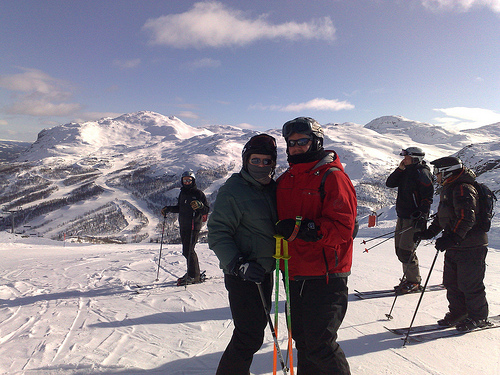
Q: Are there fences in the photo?
A: No, there are no fences.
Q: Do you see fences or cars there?
A: No, there are no fences or cars.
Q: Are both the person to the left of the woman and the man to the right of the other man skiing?
A: Yes, both the person and the man are skiing.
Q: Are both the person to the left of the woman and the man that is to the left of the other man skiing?
A: Yes, both the person and the man are skiing.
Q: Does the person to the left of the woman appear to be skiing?
A: Yes, the person is skiing.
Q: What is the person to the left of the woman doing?
A: The person is skiing.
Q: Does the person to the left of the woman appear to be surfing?
A: No, the person is skiing.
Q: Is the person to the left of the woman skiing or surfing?
A: The person is skiing.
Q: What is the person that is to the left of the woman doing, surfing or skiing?
A: The person is skiing.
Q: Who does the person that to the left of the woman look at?
A: The person looks at the man.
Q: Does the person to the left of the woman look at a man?
A: Yes, the person looks at a man.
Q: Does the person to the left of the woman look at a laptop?
A: No, the person looks at a man.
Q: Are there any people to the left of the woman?
A: Yes, there is a person to the left of the woman.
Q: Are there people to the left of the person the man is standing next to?
A: Yes, there is a person to the left of the woman.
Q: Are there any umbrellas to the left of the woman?
A: No, there is a person to the left of the woman.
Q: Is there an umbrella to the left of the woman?
A: No, there is a person to the left of the woman.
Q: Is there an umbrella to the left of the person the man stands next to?
A: No, there is a person to the left of the woman.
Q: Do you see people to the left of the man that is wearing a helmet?
A: Yes, there is a person to the left of the man.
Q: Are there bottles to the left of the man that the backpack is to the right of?
A: No, there is a person to the left of the man.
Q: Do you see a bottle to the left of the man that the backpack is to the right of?
A: No, there is a person to the left of the man.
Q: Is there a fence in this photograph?
A: No, there are no fences.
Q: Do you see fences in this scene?
A: No, there are no fences.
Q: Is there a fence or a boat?
A: No, there are no fences or boats.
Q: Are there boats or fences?
A: No, there are no fences or boats.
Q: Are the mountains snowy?
A: Yes, the mountains are snowy.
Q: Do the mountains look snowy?
A: Yes, the mountains are snowy.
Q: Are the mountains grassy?
A: No, the mountains are snowy.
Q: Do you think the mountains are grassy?
A: No, the mountains are snowy.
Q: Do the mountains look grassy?
A: No, the mountains are snowy.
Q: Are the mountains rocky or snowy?
A: The mountains are snowy.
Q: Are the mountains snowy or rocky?
A: The mountains are snowy.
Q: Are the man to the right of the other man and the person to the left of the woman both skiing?
A: Yes, both the man and the person are skiing.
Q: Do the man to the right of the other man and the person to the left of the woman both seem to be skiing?
A: Yes, both the man and the person are skiing.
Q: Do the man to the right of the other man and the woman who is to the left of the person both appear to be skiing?
A: Yes, both the man and the woman are skiing.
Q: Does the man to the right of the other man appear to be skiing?
A: Yes, the man is skiing.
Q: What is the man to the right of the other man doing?
A: The man is skiing.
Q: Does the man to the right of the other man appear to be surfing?
A: No, the man is skiing.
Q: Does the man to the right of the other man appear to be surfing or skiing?
A: The man is skiing.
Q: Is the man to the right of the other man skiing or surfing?
A: The man is skiing.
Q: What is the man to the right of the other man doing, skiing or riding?
A: The man is skiing.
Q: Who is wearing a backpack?
A: The man is wearing a backpack.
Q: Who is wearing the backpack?
A: The man is wearing a backpack.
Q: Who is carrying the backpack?
A: The man is carrying the backpack.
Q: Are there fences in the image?
A: No, there are no fences.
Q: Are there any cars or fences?
A: No, there are no fences or cars.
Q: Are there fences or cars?
A: No, there are no fences or cars.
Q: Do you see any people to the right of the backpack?
A: No, the person is to the left of the backpack.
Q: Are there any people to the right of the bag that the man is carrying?
A: No, the person is to the left of the backpack.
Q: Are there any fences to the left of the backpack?
A: No, there is a person to the left of the backpack.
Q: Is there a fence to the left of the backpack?
A: No, there is a person to the left of the backpack.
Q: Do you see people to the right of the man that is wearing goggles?
A: Yes, there is a person to the right of the man.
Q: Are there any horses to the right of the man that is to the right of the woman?
A: No, there is a person to the right of the man.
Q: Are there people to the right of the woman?
A: Yes, there is a person to the right of the woman.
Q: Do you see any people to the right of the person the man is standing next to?
A: Yes, there is a person to the right of the woman.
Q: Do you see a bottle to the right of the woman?
A: No, there is a person to the right of the woman.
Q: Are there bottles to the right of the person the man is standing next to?
A: No, there is a person to the right of the woman.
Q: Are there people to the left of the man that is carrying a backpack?
A: Yes, there is a person to the left of the man.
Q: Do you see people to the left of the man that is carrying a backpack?
A: Yes, there is a person to the left of the man.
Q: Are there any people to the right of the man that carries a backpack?
A: No, the person is to the left of the man.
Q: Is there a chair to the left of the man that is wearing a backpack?
A: No, there is a person to the left of the man.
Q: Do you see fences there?
A: No, there are no fences.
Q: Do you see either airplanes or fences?
A: No, there are no fences or airplanes.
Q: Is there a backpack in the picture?
A: Yes, there is a backpack.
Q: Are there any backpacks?
A: Yes, there is a backpack.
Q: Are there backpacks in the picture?
A: Yes, there is a backpack.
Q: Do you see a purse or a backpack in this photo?
A: Yes, there is a backpack.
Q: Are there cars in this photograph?
A: No, there are no cars.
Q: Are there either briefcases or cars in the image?
A: No, there are no cars or briefcases.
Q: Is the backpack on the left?
A: No, the backpack is on the right of the image.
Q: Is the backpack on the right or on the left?
A: The backpack is on the right of the image.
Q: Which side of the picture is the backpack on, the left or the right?
A: The backpack is on the right of the image.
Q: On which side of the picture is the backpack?
A: The backpack is on the right of the image.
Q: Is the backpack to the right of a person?
A: Yes, the backpack is to the right of a person.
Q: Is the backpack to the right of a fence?
A: No, the backpack is to the right of a person.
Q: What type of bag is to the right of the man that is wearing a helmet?
A: The bag is a backpack.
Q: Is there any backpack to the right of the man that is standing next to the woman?
A: Yes, there is a backpack to the right of the man.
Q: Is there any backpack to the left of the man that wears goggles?
A: No, the backpack is to the right of the man.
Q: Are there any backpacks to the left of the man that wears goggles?
A: No, the backpack is to the right of the man.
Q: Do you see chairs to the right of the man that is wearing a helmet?
A: No, there is a backpack to the right of the man.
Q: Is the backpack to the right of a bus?
A: No, the backpack is to the right of a man.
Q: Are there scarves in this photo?
A: Yes, there is a scarf.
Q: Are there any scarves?
A: Yes, there is a scarf.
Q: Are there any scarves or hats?
A: Yes, there is a scarf.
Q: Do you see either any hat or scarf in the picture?
A: Yes, there is a scarf.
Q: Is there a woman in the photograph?
A: Yes, there is a woman.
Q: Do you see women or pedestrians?
A: Yes, there is a woman.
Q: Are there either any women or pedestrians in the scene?
A: Yes, there is a woman.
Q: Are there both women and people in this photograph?
A: Yes, there are both a woman and a person.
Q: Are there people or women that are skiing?
A: Yes, the woman is skiing.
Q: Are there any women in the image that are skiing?
A: Yes, there is a woman that is skiing.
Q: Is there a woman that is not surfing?
A: Yes, there is a woman that is skiing.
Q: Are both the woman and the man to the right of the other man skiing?
A: Yes, both the woman and the man are skiing.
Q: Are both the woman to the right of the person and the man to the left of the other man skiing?
A: Yes, both the woman and the man are skiing.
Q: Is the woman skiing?
A: Yes, the woman is skiing.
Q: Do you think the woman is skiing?
A: Yes, the woman is skiing.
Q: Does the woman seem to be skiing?
A: Yes, the woman is skiing.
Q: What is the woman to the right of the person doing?
A: The woman is skiing.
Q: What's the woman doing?
A: The woman is skiing.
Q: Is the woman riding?
A: No, the woman is skiing.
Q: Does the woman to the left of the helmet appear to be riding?
A: No, the woman is skiing.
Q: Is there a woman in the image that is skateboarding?
A: No, there is a woman but she is skiing.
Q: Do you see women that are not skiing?
A: No, there is a woman but she is skiing.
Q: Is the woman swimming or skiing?
A: The woman is skiing.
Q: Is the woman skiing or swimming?
A: The woman is skiing.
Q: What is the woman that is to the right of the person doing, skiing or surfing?
A: The woman is skiing.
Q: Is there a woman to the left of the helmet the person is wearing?
A: Yes, there is a woman to the left of the helmet.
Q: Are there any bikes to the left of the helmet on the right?
A: No, there is a woman to the left of the helmet.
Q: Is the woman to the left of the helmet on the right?
A: Yes, the woman is to the left of the helmet.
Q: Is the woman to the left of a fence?
A: No, the woman is to the left of the helmet.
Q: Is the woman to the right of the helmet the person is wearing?
A: No, the woman is to the left of the helmet.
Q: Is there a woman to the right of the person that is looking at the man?
A: Yes, there is a woman to the right of the person.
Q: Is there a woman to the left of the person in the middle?
A: No, the woman is to the right of the person.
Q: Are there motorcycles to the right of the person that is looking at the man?
A: No, there is a woman to the right of the person.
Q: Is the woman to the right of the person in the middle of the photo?
A: Yes, the woman is to the right of the person.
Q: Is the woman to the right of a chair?
A: No, the woman is to the right of the person.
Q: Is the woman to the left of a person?
A: No, the woman is to the right of a person.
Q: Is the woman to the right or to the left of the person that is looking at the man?
A: The woman is to the right of the person.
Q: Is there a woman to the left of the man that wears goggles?
A: Yes, there is a woman to the left of the man.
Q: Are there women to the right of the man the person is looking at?
A: No, the woman is to the left of the man.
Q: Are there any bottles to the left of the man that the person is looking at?
A: No, there is a woman to the left of the man.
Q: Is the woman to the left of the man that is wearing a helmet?
A: Yes, the woman is to the left of the man.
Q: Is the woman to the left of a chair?
A: No, the woman is to the left of the man.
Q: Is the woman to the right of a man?
A: No, the woman is to the left of a man.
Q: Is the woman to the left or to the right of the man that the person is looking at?
A: The woman is to the left of the man.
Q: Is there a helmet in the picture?
A: Yes, there is a helmet.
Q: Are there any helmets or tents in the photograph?
A: Yes, there is a helmet.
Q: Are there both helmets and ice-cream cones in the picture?
A: No, there is a helmet but no ice-cream cones.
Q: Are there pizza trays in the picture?
A: No, there are no pizza trays.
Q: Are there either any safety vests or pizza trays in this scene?
A: No, there are no pizza trays or safety vests.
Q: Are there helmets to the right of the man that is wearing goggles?
A: Yes, there is a helmet to the right of the man.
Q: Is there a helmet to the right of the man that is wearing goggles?
A: Yes, there is a helmet to the right of the man.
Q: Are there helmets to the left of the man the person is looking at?
A: No, the helmet is to the right of the man.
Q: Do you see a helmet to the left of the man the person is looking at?
A: No, the helmet is to the right of the man.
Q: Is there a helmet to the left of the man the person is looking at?
A: No, the helmet is to the right of the man.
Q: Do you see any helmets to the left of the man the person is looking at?
A: No, the helmet is to the right of the man.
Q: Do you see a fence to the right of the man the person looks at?
A: No, there is a helmet to the right of the man.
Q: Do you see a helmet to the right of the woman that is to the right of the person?
A: Yes, there is a helmet to the right of the woman.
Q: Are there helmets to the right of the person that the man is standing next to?
A: Yes, there is a helmet to the right of the woman.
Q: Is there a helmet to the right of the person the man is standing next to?
A: Yes, there is a helmet to the right of the woman.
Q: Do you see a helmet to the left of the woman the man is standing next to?
A: No, the helmet is to the right of the woman.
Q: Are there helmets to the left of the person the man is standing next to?
A: No, the helmet is to the right of the woman.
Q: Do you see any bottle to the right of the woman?
A: No, there is a helmet to the right of the woman.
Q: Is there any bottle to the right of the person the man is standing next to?
A: No, there is a helmet to the right of the woman.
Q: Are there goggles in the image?
A: Yes, there are goggles.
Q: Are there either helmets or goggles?
A: Yes, there are goggles.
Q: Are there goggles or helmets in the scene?
A: Yes, there are goggles.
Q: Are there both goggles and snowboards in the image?
A: No, there are goggles but no snowboards.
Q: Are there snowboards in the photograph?
A: No, there are no snowboards.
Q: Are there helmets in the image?
A: Yes, there is a helmet.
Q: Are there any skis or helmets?
A: Yes, there is a helmet.